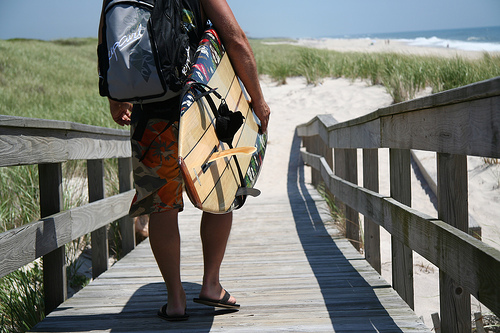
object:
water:
[310, 25, 499, 52]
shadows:
[287, 127, 406, 333]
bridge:
[0, 74, 499, 333]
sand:
[254, 37, 500, 333]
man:
[97, 0, 276, 322]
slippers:
[191, 287, 240, 310]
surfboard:
[173, 53, 268, 218]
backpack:
[97, 0, 199, 108]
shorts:
[129, 108, 185, 217]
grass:
[0, 38, 498, 331]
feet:
[198, 282, 236, 304]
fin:
[206, 146, 257, 165]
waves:
[324, 35, 500, 51]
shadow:
[29, 281, 221, 332]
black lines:
[180, 74, 241, 162]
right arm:
[201, 1, 272, 108]